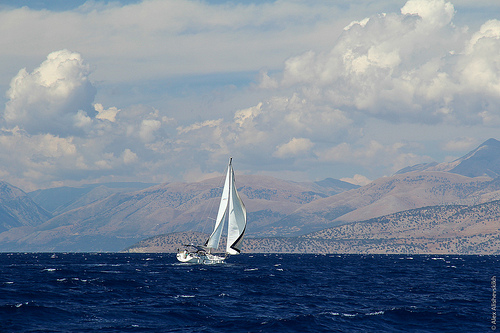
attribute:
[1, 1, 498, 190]
sky — blue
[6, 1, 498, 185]
clouds — large, white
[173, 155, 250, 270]
boat — small, white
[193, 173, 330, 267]
lining — black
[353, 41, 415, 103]
cloud — white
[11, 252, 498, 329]
blue water — dark blue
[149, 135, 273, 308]
boat — is wind-powered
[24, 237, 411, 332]
sea — deep, blue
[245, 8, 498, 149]
clouds — white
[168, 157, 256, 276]
sailboat — white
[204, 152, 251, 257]
sails — white, tall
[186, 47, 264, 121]
sky — blue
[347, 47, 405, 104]
clouds — white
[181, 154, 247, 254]
sails — black, white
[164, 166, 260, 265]
boat — a sailboat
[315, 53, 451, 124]
clouds — white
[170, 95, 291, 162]
clouds — white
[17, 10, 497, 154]
sky — blue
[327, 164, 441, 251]
mountains — brown